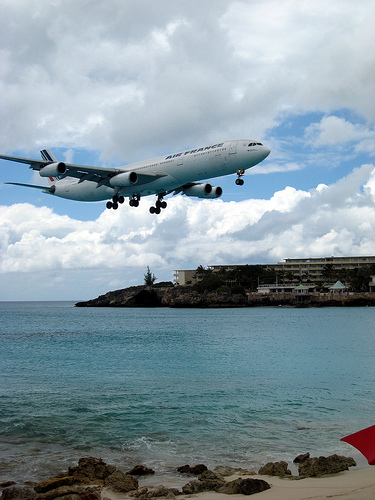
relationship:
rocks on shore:
[87, 282, 138, 316] [165, 285, 310, 328]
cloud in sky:
[188, 20, 255, 96] [94, 64, 365, 295]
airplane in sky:
[27, 129, 236, 231] [94, 64, 365, 295]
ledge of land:
[152, 298, 297, 319] [90, 249, 332, 300]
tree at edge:
[134, 262, 166, 299] [27, 240, 170, 319]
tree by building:
[134, 262, 166, 299] [200, 227, 324, 293]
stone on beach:
[181, 461, 237, 487] [19, 436, 370, 479]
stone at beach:
[181, 461, 237, 487] [19, 436, 370, 479]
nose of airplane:
[232, 119, 279, 204] [0, 138, 271, 215]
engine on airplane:
[92, 167, 169, 212] [0, 138, 271, 215]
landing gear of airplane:
[220, 165, 264, 199] [0, 138, 271, 215]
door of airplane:
[216, 132, 272, 197] [0, 138, 271, 215]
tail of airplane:
[28, 176, 73, 202] [0, 138, 271, 215]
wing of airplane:
[8, 132, 143, 202] [0, 138, 271, 215]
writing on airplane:
[203, 140, 250, 179] [0, 138, 271, 215]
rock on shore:
[177, 462, 216, 477] [165, 285, 310, 328]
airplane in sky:
[0, 138, 271, 215] [94, 64, 365, 295]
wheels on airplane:
[147, 178, 176, 247] [0, 138, 271, 215]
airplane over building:
[27, 129, 236, 231] [200, 227, 324, 293]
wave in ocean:
[42, 382, 125, 443] [50, 296, 130, 443]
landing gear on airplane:
[220, 165, 264, 199] [0, 138, 271, 215]